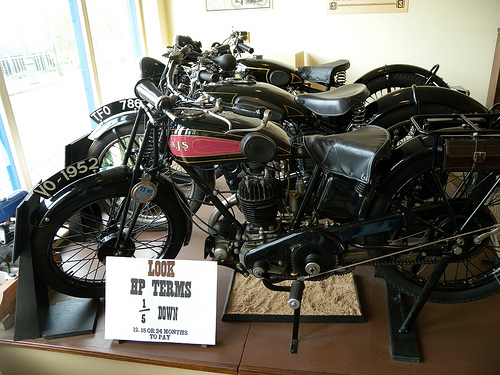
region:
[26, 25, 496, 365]
three shiny motorcycles in a window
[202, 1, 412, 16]
two pictures hanging on a wall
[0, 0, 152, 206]
storefront windows glowing in the sunlight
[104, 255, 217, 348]
a small sign with payment information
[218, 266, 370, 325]
a small black tray with sawdust in it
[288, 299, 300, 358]
a small black metal kickstand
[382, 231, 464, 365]
a black metal stand supporting a motorcycle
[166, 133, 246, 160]
a red and gold accent on a black motorcycle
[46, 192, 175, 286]
very thin black metal spokes inside a tire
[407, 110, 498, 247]
a black metal rack for storage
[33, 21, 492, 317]
bikes in a shop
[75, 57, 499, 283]
these motorcycles are no display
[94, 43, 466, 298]
there are four bikes in the scene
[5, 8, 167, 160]
the display window for the motorbikes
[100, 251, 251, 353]
an advertisement for the bike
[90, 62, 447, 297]
all of the bikes are black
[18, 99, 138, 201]
there are numbers on the tire covers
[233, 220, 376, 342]
a wooden platform is underneath the bike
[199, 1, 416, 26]
the bottom of two pictures on the wall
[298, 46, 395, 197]
these are the motorcycle's seats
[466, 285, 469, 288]
part of a wheel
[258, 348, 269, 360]
part of a surface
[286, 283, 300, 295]
part of a pedal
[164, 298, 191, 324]
part of a board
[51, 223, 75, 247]
part of a wheel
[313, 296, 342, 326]
part of a sand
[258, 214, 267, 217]
part of an engine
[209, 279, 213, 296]
edge of a board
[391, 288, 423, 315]
part of a wheel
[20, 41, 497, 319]
Motorcycles in a store window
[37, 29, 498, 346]
Three motorcycles in a row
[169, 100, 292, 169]
A red and black tank on a motorcycle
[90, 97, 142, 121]
A sign that says TFO 786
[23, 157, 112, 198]
A sign that says VO-1952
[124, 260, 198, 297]
A sign that says Look HP Terms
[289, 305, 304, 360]
A kickstand on a motorcycle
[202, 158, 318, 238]
An engine on a motorcycle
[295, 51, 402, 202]
Three seats in a row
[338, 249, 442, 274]
A chain on a motorcycle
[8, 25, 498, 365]
Motorcycles are ready for sale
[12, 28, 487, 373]
Motorcycles are in a display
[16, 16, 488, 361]
Motorcycles are inside a dealership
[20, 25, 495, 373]
Motorcycles are being offered for sale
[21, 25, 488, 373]
Motorcycles are inside a room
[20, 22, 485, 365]
Motorcycles that are being sold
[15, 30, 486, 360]
Motorcycles with big powerful engines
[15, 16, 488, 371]
Motorcycles that are for street riding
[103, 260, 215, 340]
A sign that is in a motorcycle shop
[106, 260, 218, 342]
A sign showing terms in a motorcycle dealership